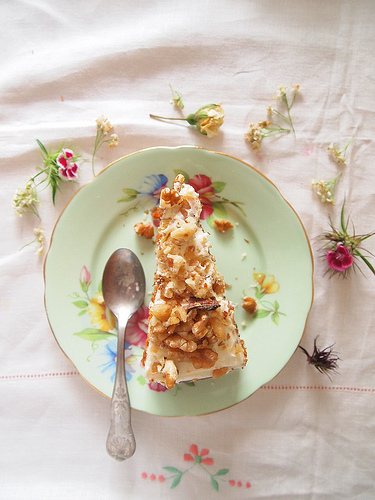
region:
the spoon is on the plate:
[101, 249, 145, 460]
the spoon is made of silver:
[94, 246, 148, 459]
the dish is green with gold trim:
[42, 143, 317, 419]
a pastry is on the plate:
[143, 182, 244, 391]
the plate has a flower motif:
[76, 258, 191, 398]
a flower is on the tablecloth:
[151, 88, 226, 139]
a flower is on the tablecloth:
[319, 204, 374, 277]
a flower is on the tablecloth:
[32, 138, 79, 187]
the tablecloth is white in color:
[2, 1, 371, 496]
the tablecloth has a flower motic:
[139, 440, 249, 494]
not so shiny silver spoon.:
[96, 245, 150, 461]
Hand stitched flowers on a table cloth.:
[139, 439, 256, 494]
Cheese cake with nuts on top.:
[142, 174, 253, 399]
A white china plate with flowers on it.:
[42, 142, 318, 419]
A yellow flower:
[140, 90, 235, 140]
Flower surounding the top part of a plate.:
[12, 81, 372, 282]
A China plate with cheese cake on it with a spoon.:
[31, 141, 318, 464]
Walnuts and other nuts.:
[154, 290, 231, 360]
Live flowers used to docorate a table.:
[2, 79, 368, 465]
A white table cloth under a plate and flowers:
[12, 76, 371, 469]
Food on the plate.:
[71, 142, 309, 418]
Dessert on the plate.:
[99, 176, 286, 427]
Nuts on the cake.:
[135, 206, 238, 408]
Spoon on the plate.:
[89, 250, 188, 499]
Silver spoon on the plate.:
[88, 243, 156, 466]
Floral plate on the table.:
[30, 148, 359, 485]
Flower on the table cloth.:
[121, 444, 239, 499]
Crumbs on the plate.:
[210, 205, 283, 318]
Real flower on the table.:
[25, 122, 94, 206]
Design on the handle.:
[98, 369, 137, 467]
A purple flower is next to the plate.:
[307, 213, 361, 282]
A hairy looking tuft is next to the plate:
[305, 331, 341, 382]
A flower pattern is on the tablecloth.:
[141, 439, 255, 485]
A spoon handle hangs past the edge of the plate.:
[101, 391, 133, 460]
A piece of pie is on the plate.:
[150, 172, 246, 387]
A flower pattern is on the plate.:
[197, 168, 235, 215]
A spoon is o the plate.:
[103, 246, 146, 459]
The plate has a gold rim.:
[306, 236, 315, 305]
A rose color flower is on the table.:
[135, 103, 234, 138]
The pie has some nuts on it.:
[166, 243, 219, 371]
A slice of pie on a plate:
[20, 138, 355, 495]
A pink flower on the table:
[11, 112, 80, 219]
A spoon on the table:
[78, 239, 151, 472]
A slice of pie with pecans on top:
[151, 161, 244, 389]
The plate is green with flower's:
[39, 144, 313, 422]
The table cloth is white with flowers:
[248, 412, 362, 496]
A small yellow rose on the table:
[141, 83, 235, 138]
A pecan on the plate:
[238, 291, 262, 317]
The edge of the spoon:
[103, 351, 138, 463]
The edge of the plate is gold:
[213, 144, 318, 380]